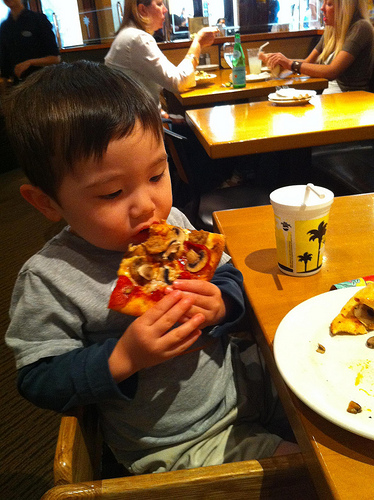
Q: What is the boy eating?
A: Pizza.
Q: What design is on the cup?
A: Trees.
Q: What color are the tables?
A: Brown.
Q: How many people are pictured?
A: Four.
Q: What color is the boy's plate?
A: White.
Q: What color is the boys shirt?
A: Grey.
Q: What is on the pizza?
A: Mushrooms.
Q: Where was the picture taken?
A: At a restaurant.